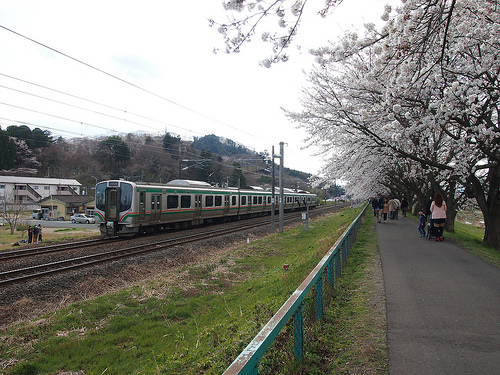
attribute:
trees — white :
[14, 118, 289, 192]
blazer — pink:
[430, 201, 450, 221]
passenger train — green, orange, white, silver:
[92, 175, 318, 239]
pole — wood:
[276, 143, 289, 228]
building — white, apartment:
[0, 179, 80, 204]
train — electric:
[109, 163, 314, 245]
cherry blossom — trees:
[208, 0, 498, 208]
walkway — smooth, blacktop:
[370, 197, 499, 374]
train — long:
[97, 176, 317, 236]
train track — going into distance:
[1, 200, 361, 287]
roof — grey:
[30, 174, 104, 211]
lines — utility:
[3, 20, 292, 189]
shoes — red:
[408, 226, 462, 294]